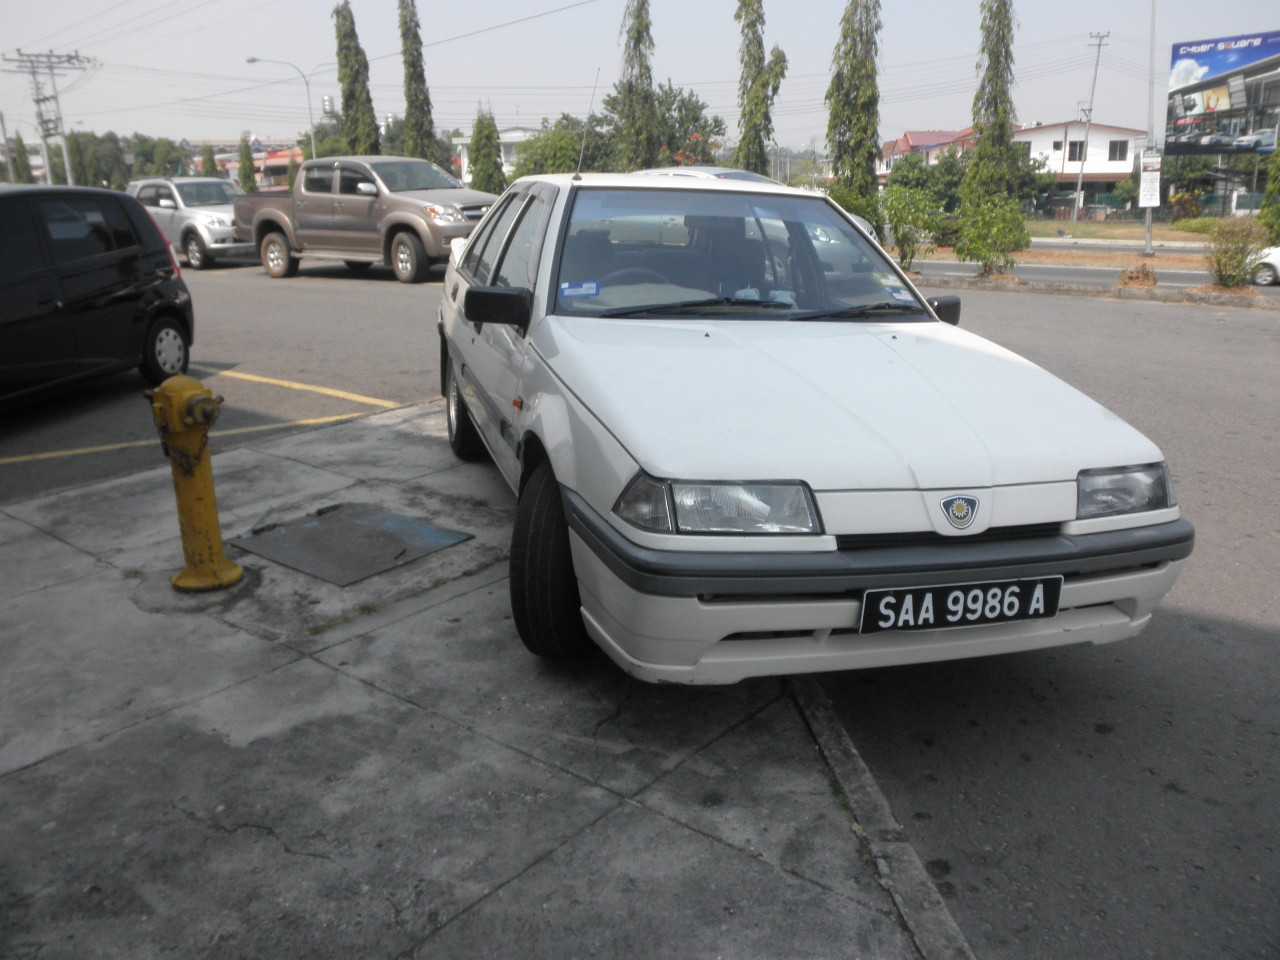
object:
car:
[435, 173, 1193, 687]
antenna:
[570, 68, 602, 181]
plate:
[859, 575, 1064, 637]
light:
[610, 468, 823, 537]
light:
[1076, 460, 1177, 521]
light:
[425, 205, 468, 226]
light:
[207, 217, 227, 227]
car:
[0, 186, 195, 422]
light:
[167, 244, 181, 279]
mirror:
[464, 287, 534, 328]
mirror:
[926, 295, 961, 326]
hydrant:
[144, 375, 244, 592]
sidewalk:
[0, 365, 981, 960]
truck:
[232, 154, 502, 283]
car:
[124, 176, 258, 270]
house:
[821, 120, 1162, 220]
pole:
[2, 48, 101, 188]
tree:
[953, 0, 1030, 281]